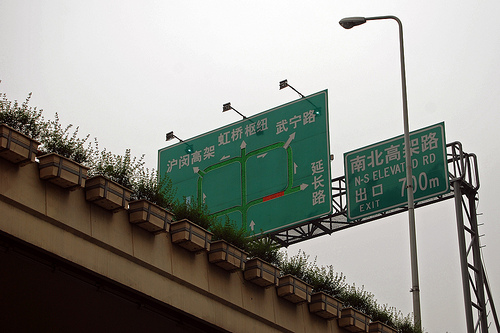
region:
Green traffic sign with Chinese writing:
[162, 96, 325, 238]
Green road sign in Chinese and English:
[343, 126, 450, 241]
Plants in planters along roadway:
[1, 100, 283, 306]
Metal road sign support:
[328, 149, 496, 331]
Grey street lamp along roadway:
[333, 7, 436, 327]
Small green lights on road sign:
[171, 95, 339, 158]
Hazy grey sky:
[73, 13, 448, 80]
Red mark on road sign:
[261, 175, 291, 220]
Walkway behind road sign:
[317, 144, 484, 252]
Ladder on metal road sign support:
[468, 202, 498, 331]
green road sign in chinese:
[342, 127, 457, 211]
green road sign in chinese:
[149, 105, 335, 242]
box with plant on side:
[171, 210, 213, 255]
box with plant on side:
[213, 234, 244, 276]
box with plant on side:
[252, 258, 277, 296]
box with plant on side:
[279, 273, 311, 305]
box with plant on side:
[314, 290, 339, 322]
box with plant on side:
[344, 308, 367, 329]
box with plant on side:
[93, 175, 130, 216]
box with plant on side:
[42, 153, 90, 190]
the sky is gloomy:
[21, 25, 161, 87]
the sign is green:
[139, 74, 342, 238]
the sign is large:
[144, 81, 356, 228]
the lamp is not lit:
[332, 7, 369, 44]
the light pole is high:
[319, 6, 434, 319]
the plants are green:
[114, 155, 207, 216]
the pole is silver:
[382, 74, 430, 329]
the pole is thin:
[392, 95, 425, 330]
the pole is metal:
[386, 79, 432, 331]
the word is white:
[366, 157, 403, 182]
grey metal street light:
[338, 14, 421, 331]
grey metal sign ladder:
[456, 184, 486, 331]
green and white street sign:
[336, 122, 449, 218]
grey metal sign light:
[279, 80, 303, 102]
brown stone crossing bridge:
[3, 143, 419, 330]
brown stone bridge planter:
[90, 176, 132, 210]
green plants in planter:
[103, 153, 138, 183]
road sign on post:
[143, 96, 338, 239]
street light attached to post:
[341, 14, 367, 29]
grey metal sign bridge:
[252, 142, 482, 246]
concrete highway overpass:
[0, 121, 415, 330]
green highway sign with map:
[154, 88, 333, 229]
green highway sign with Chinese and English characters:
[340, 121, 452, 220]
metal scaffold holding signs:
[240, 140, 495, 332]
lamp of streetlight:
[336, 14, 368, 28]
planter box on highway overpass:
[38, 113, 90, 190]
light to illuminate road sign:
[162, 129, 196, 155]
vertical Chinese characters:
[307, 155, 327, 210]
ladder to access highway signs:
[451, 174, 493, 331]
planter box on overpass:
[172, 179, 212, 248]